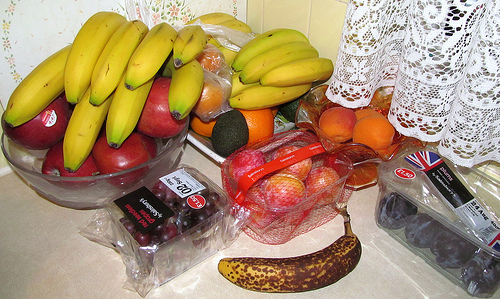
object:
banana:
[218, 205, 363, 293]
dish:
[186, 111, 295, 165]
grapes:
[123, 221, 137, 234]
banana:
[265, 58, 333, 86]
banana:
[63, 11, 127, 105]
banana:
[2, 44, 72, 128]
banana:
[63, 84, 115, 172]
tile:
[243, 0, 310, 41]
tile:
[307, 0, 349, 45]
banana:
[239, 41, 320, 85]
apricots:
[352, 115, 395, 150]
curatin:
[324, 0, 499, 168]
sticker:
[41, 110, 57, 128]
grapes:
[135, 230, 152, 246]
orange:
[234, 108, 274, 150]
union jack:
[360, 129, 486, 230]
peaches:
[318, 107, 357, 144]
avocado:
[211, 110, 249, 158]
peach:
[318, 107, 357, 143]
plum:
[377, 192, 418, 230]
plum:
[404, 213, 445, 248]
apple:
[91, 128, 157, 190]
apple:
[42, 140, 99, 191]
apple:
[0, 98, 71, 149]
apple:
[136, 75, 188, 139]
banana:
[161, 56, 203, 120]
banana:
[105, 77, 150, 145]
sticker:
[186, 194, 206, 209]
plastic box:
[103, 166, 232, 256]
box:
[76, 163, 256, 297]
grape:
[158, 224, 180, 243]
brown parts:
[326, 259, 334, 263]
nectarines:
[247, 173, 306, 212]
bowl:
[0, 113, 190, 210]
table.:
[16, 251, 66, 281]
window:
[424, 1, 499, 194]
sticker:
[404, 151, 500, 252]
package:
[76, 164, 257, 298]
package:
[221, 127, 355, 245]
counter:
[0, 143, 500, 299]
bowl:
[323, 142, 384, 191]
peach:
[354, 115, 395, 151]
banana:
[231, 28, 311, 72]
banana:
[228, 82, 313, 110]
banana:
[173, 25, 208, 68]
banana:
[89, 20, 149, 106]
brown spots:
[269, 276, 279, 282]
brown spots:
[235, 264, 240, 269]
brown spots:
[227, 274, 230, 277]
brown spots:
[230, 272, 233, 274]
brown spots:
[262, 267, 268, 274]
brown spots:
[227, 265, 229, 267]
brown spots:
[269, 269, 273, 273]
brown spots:
[243, 265, 248, 272]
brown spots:
[240, 259, 247, 264]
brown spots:
[231, 276, 234, 279]